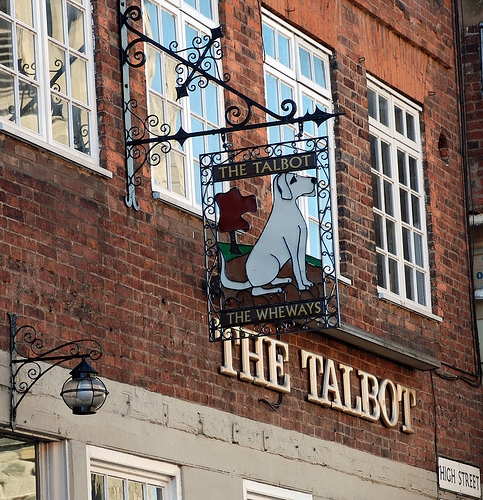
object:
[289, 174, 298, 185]
eye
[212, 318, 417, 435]
lettering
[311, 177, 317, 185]
dog nose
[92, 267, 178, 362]
wall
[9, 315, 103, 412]
hanger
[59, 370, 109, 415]
light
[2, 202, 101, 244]
wall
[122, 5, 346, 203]
sign hanger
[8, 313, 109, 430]
lamp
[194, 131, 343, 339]
yes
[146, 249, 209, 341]
wall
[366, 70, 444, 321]
window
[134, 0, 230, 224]
windows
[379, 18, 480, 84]
wall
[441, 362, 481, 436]
building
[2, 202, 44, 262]
brick wall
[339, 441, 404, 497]
wall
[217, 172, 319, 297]
dog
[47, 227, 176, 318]
ground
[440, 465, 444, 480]
letters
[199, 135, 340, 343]
sign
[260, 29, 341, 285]
window